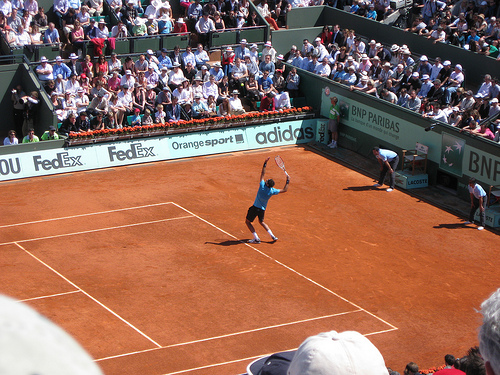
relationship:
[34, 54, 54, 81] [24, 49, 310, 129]
spectators are in stands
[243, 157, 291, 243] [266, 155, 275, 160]
man serving ball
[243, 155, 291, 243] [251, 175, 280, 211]
man wearing shirt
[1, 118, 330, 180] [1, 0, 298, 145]
advertising on stands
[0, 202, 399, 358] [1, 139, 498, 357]
lines are marking court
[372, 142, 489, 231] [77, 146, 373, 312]
judges watch match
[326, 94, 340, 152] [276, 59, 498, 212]
man standing against wall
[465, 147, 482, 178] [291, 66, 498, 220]
letter on wall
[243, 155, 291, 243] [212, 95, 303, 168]
man serving ball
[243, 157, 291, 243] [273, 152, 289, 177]
man has tennis racket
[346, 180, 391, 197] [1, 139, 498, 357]
shadows on court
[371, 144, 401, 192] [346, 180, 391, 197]
man has shadows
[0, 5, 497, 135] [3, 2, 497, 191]
spectators in stands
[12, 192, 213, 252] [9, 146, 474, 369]
line on tennis court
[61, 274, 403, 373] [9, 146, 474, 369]
line on tennis court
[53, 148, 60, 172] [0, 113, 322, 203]
letter on wall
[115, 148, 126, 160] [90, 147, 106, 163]
black letter on wall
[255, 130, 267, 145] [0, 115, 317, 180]
letter on wall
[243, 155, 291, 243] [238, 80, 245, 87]
man serving ball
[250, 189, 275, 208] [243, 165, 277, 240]
shirt on man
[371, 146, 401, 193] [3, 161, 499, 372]
man on court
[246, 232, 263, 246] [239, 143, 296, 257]
sock on tennis player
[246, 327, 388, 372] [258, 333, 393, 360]
spectator's cap on head